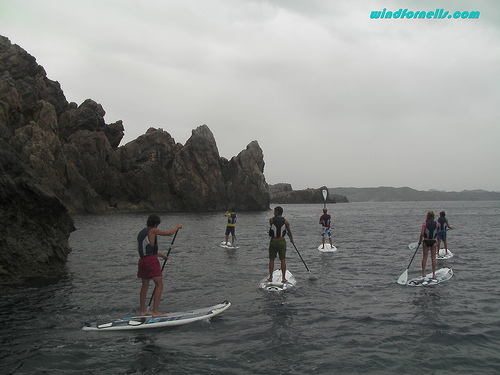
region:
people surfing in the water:
[80, 181, 474, 358]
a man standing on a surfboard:
[85, 216, 233, 336]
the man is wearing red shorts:
[132, 257, 164, 283]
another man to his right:
[254, 204, 311, 301]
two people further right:
[392, 209, 454, 296]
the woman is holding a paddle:
[386, 207, 443, 293]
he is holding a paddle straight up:
[311, 177, 338, 252]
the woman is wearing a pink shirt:
[417, 219, 444, 246]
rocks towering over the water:
[0, 25, 347, 309]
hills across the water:
[320, 179, 497, 201]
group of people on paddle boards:
[96, 205, 453, 333]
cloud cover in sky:
[17, 2, 497, 191]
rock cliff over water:
[232, 140, 269, 212]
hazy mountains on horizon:
[331, 186, 495, 203]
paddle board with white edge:
[85, 300, 230, 331]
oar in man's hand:
[289, 233, 318, 283]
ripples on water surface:
[44, 198, 499, 373]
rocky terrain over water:
[2, 82, 266, 277]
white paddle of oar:
[394, 267, 415, 288]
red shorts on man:
[135, 253, 160, 280]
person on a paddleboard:
[77, 206, 232, 336]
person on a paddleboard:
[257, 202, 309, 297]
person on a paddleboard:
[212, 204, 244, 253]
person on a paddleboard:
[310, 183, 342, 255]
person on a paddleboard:
[392, 207, 454, 289]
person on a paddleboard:
[407, 209, 456, 261]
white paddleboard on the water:
[82, 294, 231, 341]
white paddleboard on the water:
[257, 265, 295, 296]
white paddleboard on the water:
[409, 265, 454, 288]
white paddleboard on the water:
[316, 239, 338, 253]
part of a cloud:
[279, 23, 348, 123]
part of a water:
[266, 297, 339, 354]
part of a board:
[173, 304, 190, 324]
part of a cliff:
[23, 227, 50, 259]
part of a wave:
[281, 303, 343, 365]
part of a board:
[146, 273, 203, 334]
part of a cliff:
[26, 212, 75, 249]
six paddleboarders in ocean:
[80, 175, 462, 344]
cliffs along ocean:
[3, 33, 343, 348]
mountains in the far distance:
[290, 170, 496, 206]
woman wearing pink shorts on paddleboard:
[71, 200, 231, 338]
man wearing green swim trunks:
[248, 209, 314, 292]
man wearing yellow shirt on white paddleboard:
[212, 201, 247, 258]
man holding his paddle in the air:
[305, 184, 342, 251]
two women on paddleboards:
[399, 210, 468, 293]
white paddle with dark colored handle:
[391, 235, 427, 287]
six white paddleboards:
[78, 223, 465, 365]